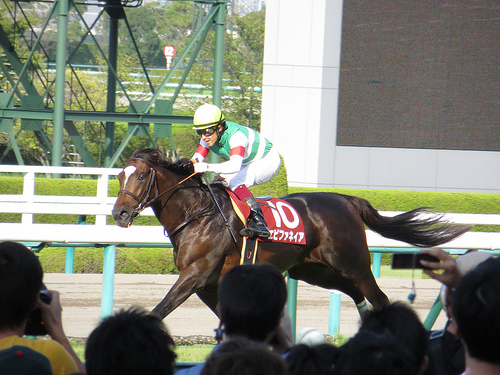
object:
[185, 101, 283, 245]
jockey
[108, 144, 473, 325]
horse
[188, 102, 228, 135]
helmet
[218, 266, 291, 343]
spectator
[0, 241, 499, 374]
crowd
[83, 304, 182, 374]
person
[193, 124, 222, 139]
goggles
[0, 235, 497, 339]
fence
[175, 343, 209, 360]
grass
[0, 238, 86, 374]
man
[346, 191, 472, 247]
tail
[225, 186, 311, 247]
blanket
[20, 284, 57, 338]
camera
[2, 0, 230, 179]
tower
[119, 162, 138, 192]
spot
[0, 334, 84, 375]
shirt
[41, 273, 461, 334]
track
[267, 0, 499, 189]
wall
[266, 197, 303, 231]
number